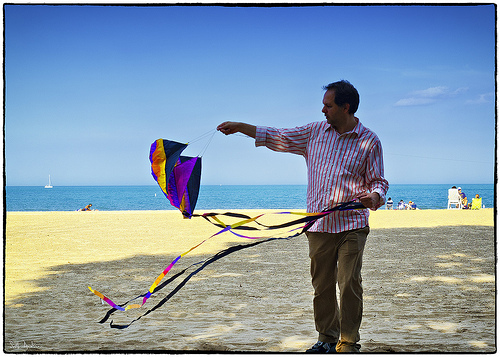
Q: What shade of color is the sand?
A: Brown.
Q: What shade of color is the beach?
A: Brown.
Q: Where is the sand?
A: On the beach.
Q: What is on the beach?
A: Sand.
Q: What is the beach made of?
A: Sand.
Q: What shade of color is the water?
A: Blue.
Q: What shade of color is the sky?
A: Blue.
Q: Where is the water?
A: In the ocean.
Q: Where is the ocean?
A: Beyond the beach.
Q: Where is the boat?
A: In the water.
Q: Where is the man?
A: On the beach.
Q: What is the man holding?
A: A kite.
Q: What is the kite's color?
A: Multi.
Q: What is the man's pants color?
A: Tan.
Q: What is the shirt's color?
A: Red and white.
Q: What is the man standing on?
A: Sand.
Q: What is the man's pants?
A: Khaki.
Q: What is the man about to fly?
A: Kite.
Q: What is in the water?
A: Boat.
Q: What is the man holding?
A: A kite.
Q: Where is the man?
A: Beach.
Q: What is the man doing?
A: Holding a kite.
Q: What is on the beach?
A: Sand.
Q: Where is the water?
A: Past the sand.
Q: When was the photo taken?
A: Daytime.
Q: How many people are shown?
A: One.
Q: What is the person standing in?
A: Sand.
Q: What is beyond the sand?
A: Water.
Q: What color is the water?
A: Blue.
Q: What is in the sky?
A: Clouds.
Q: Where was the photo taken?
A: At the Beach.